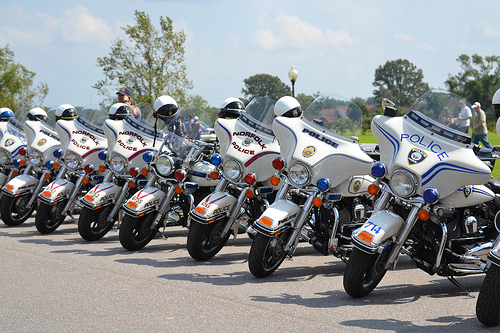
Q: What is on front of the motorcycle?
A: Black wheels.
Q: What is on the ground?
A: Grey asphalt.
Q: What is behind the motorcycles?
A: Trees.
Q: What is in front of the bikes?
A: Paved road.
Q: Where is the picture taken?
A: A parking lot.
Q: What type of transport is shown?
A: Motorcycles.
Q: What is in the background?
A: Trees.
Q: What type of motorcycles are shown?
A: Police.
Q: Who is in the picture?
A: A policeman.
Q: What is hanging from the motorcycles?
A: Helmets.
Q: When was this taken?
A: Daytime.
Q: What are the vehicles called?
A: Motorcycles.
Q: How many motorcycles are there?
A: 8.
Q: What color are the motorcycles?
A: White.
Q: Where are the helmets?
A: On the handlebars.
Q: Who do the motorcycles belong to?
A: Police.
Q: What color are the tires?
A: Black.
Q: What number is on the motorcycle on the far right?
A: 714.